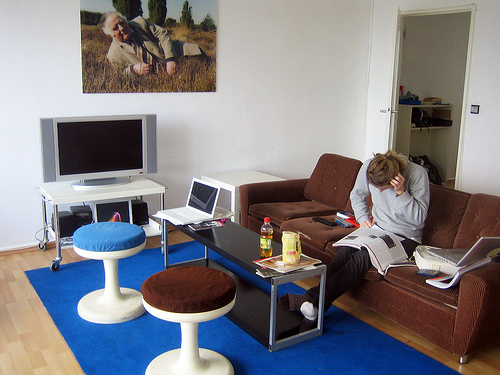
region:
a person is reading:
[317, 133, 417, 325]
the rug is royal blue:
[50, 243, 375, 370]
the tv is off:
[1, 112, 173, 175]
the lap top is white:
[147, 172, 227, 237]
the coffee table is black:
[145, 200, 314, 281]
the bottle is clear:
[252, 205, 276, 262]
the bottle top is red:
[255, 210, 275, 229]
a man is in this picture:
[75, 1, 225, 98]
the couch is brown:
[252, 127, 474, 355]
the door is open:
[366, 0, 437, 170]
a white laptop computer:
[180, 165, 230, 225]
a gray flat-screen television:
[37, 102, 180, 169]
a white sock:
[301, 289, 327, 311]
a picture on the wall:
[99, 32, 215, 69]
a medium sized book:
[327, 206, 381, 267]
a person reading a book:
[346, 162, 409, 217]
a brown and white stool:
[115, 258, 240, 331]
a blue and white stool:
[94, 228, 124, 248]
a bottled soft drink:
[251, 217, 277, 264]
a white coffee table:
[224, 158, 272, 178]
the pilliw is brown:
[132, 265, 242, 327]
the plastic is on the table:
[245, 216, 280, 256]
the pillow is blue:
[71, 219, 148, 252]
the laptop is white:
[170, 179, 222, 224]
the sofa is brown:
[256, 167, 496, 311]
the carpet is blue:
[323, 339, 378, 374]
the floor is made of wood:
[12, 317, 45, 374]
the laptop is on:
[160, 185, 222, 237]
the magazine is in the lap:
[345, 222, 405, 267]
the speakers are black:
[63, 205, 154, 220]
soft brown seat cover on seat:
[150, 267, 241, 324]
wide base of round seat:
[68, 286, 155, 333]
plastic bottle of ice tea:
[243, 208, 280, 263]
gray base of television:
[27, 116, 164, 181]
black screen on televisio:
[65, 130, 166, 162]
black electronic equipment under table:
[53, 193, 153, 240]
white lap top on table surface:
[148, 160, 257, 252]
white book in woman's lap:
[323, 215, 435, 272]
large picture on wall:
[41, 13, 248, 90]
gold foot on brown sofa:
[448, 346, 480, 372]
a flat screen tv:
[34, 113, 162, 184]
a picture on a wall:
[74, 6, 226, 98]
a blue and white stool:
[66, 217, 143, 336]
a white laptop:
[162, 176, 218, 228]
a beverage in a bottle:
[256, 213, 273, 259]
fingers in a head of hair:
[387, 166, 414, 198]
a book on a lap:
[330, 216, 407, 281]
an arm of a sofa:
[236, 179, 307, 213]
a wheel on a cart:
[42, 253, 67, 276]